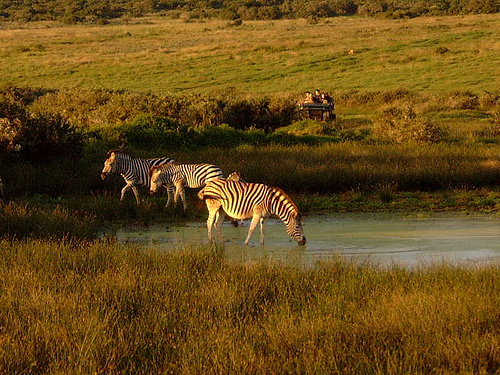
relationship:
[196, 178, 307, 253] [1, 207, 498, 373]
zebra in pasture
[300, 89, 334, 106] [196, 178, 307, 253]
people watch zebra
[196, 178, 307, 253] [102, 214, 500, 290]
zebra drinking water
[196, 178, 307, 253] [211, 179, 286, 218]
zebra has stripes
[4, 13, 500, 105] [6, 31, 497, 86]
field has grass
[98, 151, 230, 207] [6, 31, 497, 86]
zebra walking in grass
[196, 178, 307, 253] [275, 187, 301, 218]
zebra has hair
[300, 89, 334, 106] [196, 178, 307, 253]
people watching zebra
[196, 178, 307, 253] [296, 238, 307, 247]
zebra has nose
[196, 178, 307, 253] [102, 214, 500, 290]
zebra drinks water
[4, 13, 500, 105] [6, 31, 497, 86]
hillside has grass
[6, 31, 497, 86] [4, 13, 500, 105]
grass on hill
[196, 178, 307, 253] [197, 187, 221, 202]
zebra has tail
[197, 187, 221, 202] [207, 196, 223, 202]
tail has hair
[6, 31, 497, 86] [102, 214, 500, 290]
grass surrounds water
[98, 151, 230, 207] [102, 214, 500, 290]
zebra in water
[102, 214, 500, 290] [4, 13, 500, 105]
water in field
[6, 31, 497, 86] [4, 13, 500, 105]
grass on field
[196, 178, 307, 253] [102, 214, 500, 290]
zebra in water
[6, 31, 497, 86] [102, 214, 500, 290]
hill above water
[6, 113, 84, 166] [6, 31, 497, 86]
bushes near grass